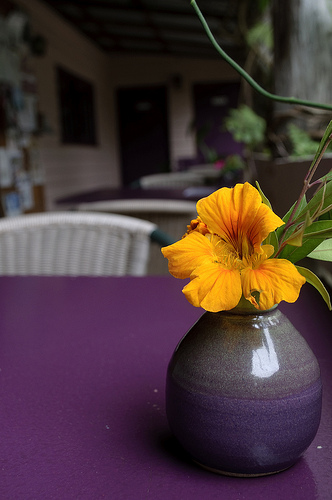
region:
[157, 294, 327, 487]
A purple flower vase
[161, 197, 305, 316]
A yellow flower in the vase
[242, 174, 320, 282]
Green leaves by the flower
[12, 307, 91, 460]
A purple tablecloth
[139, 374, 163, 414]
Crumbs on the tablecloth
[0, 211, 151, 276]
A white chair by the table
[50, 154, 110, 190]
A white wooden wall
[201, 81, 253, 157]
A purple door in the distance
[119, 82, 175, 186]
A brown door next to the purple door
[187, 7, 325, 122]
A thin green stem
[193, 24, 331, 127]
A thin green wire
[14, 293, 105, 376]
A deep purple tablecloth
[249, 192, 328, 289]
Green leaves by the yellow flower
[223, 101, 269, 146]
A small green plant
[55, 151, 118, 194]
A blank white wall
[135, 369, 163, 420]
Crumbs on the table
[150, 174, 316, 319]
This is a flower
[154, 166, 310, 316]
This is a yellow flower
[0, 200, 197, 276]
This is a seat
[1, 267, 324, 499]
This is a table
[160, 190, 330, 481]
This is a flower vase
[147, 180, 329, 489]
This is a purple flower vase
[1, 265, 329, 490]
This is a purple flower vase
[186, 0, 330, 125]
This is a wire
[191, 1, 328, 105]
This is a cable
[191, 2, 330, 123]
This is a green cable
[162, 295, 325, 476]
A small purple flower vase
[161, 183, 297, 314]
A beautiful yellow flower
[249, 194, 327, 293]
Green leaves in the vase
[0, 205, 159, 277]
A white chair next to the table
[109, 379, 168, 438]
Small crumbs on the tablecloth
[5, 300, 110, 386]
A purple tablecloth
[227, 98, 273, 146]
Small green plants in the background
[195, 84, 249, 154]
A purple door at the end of the room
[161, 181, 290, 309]
A yellow flower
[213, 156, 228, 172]
A pink flower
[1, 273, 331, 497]
A table covered by a tablecloth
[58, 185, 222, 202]
A table covered by a tablecloth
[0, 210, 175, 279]
a white wicker chair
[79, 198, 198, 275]
a white wicker chair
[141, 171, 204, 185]
a white wicker chair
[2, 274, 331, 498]
A purple tablecloth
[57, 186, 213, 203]
A purple tablecloth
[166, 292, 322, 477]
A grey and purple vase